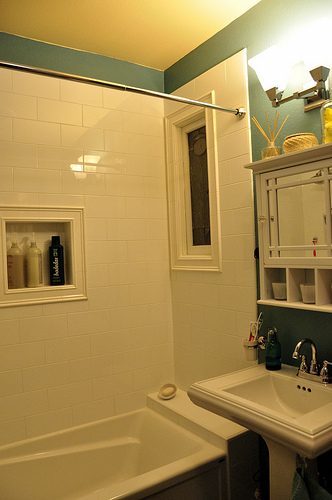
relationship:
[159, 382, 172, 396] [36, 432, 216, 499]
dish on top of tub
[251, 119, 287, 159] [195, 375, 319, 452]
bottle on top of sink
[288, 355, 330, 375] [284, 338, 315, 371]
handles attached to faucet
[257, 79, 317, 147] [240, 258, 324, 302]
candles on top of shelf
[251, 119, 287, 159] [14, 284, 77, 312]
bottle on ledge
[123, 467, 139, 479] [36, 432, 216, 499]
plug attached to tub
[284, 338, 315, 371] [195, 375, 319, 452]
faucet of sink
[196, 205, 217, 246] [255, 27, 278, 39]
mirror attached to wall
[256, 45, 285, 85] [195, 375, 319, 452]
light above sink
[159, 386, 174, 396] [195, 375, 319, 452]
soap on top of sink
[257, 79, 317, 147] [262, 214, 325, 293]
candles on top of shelves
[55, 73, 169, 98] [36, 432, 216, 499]
rod of tub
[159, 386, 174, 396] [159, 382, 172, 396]
soap inside of dish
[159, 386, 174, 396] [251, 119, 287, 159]
soap inside of bottle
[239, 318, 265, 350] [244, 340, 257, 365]
toothpaste inside of cup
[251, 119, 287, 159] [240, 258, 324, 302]
bottle on top of shelf